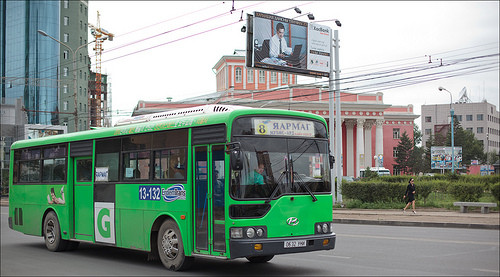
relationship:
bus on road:
[4, 106, 344, 266] [1, 197, 499, 275]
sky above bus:
[82, 2, 496, 108] [4, 106, 344, 266]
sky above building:
[82, 2, 496, 108] [126, 46, 424, 185]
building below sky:
[126, 46, 424, 185] [82, 2, 496, 108]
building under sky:
[126, 46, 424, 185] [82, 2, 496, 108]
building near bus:
[126, 46, 424, 185] [4, 106, 344, 266]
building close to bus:
[126, 46, 424, 185] [4, 106, 344, 266]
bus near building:
[4, 106, 344, 266] [126, 46, 424, 185]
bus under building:
[4, 106, 344, 266] [126, 46, 424, 185]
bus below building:
[4, 106, 344, 266] [126, 46, 424, 185]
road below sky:
[1, 197, 499, 275] [82, 2, 496, 108]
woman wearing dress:
[401, 173, 424, 209] [406, 182, 415, 203]